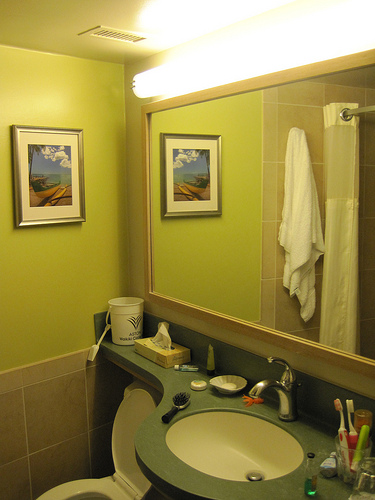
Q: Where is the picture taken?
A: Bathroom.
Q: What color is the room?
A: Green.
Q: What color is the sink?
A: White.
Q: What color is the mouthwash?
A: Blue.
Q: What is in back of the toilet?
A: Kleenex.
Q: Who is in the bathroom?
A: No one.